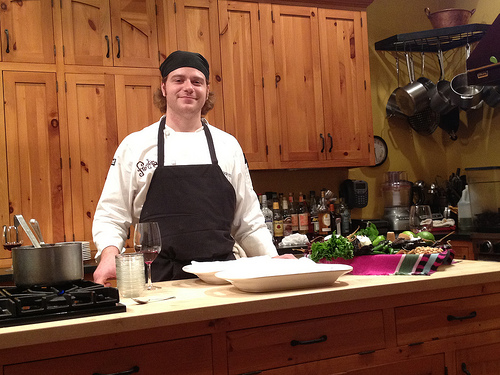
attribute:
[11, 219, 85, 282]
pot — metal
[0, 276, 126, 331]
stove — steel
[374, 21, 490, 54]
rack — metal, black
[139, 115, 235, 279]
apron — black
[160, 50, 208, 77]
bandana — black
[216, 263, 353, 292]
tray — white, large, empty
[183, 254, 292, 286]
tray — white, large, empty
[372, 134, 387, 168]
clock — black, white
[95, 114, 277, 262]
shirt — white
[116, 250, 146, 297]
can — opened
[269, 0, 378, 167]
cabinet — wooden, brown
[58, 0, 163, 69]
cabinet — wooden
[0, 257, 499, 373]
table — wooden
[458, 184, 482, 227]
gallon jug — white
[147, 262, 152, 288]
stem — long